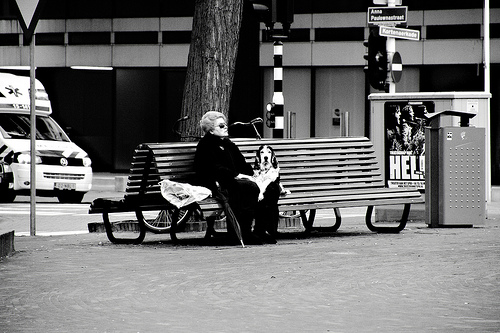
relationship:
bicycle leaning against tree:
[136, 127, 285, 227] [186, 10, 247, 145]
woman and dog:
[198, 104, 258, 242] [254, 139, 291, 200]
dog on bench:
[254, 139, 291, 200] [115, 135, 375, 219]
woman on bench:
[198, 104, 258, 242] [115, 135, 375, 219]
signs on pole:
[368, 7, 418, 78] [390, 28, 396, 89]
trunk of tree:
[181, 18, 227, 127] [186, 10, 247, 145]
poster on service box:
[389, 103, 426, 186] [373, 93, 487, 192]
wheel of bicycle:
[125, 160, 198, 241] [136, 127, 285, 227]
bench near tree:
[115, 135, 375, 219] [186, 10, 247, 145]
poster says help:
[389, 103, 426, 186] [389, 155, 428, 180]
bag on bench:
[146, 180, 221, 217] [115, 135, 375, 219]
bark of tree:
[198, 56, 218, 82] [186, 10, 247, 145]